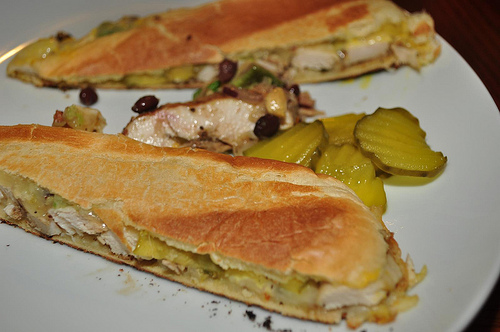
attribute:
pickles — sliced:
[270, 96, 398, 226]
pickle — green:
[354, 106, 446, 176]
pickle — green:
[316, 115, 361, 144]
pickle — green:
[242, 121, 323, 165]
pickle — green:
[309, 141, 386, 211]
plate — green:
[1, 0, 496, 329]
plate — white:
[424, 171, 478, 301]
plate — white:
[452, 40, 489, 157]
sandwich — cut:
[14, 31, 452, 329]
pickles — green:
[355, 105, 445, 175]